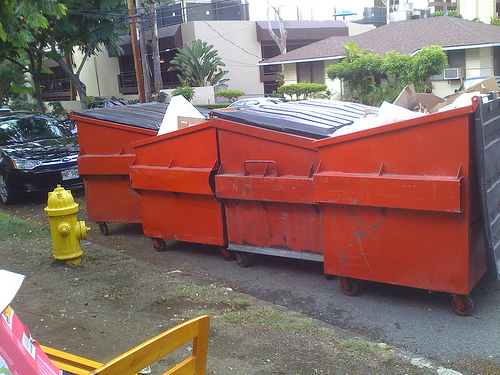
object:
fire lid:
[72, 101, 212, 133]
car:
[0, 103, 86, 206]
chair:
[30, 310, 214, 374]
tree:
[323, 39, 385, 113]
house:
[257, 14, 500, 108]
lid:
[212, 97, 385, 137]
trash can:
[310, 74, 500, 315]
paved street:
[0, 196, 500, 374]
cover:
[212, 98, 381, 141]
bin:
[209, 98, 387, 270]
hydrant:
[41, 182, 94, 266]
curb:
[0, 209, 462, 374]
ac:
[443, 67, 464, 82]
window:
[444, 49, 465, 68]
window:
[311, 60, 323, 86]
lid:
[475, 90, 500, 284]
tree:
[1, 0, 68, 114]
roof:
[257, 17, 500, 67]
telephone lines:
[180, 0, 274, 70]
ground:
[0, 195, 500, 374]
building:
[68, 19, 379, 102]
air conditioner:
[442, 65, 461, 81]